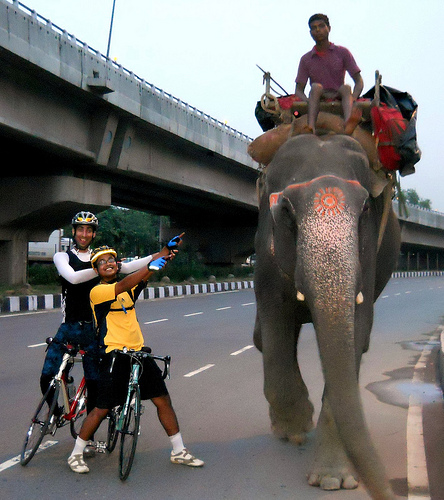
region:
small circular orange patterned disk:
[313, 183, 352, 227]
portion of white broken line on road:
[150, 303, 238, 327]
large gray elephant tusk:
[286, 173, 418, 499]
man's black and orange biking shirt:
[82, 278, 159, 361]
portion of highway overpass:
[193, 98, 243, 214]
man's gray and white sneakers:
[169, 449, 207, 473]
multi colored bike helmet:
[68, 205, 113, 232]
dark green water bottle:
[110, 405, 131, 439]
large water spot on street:
[366, 363, 443, 423]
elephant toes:
[298, 462, 374, 498]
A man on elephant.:
[240, 11, 403, 494]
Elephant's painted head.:
[268, 133, 392, 498]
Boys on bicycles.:
[16, 211, 208, 495]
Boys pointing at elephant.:
[49, 208, 201, 309]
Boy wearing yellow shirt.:
[85, 281, 167, 355]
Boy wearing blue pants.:
[37, 318, 99, 383]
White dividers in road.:
[145, 295, 249, 328]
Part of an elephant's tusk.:
[292, 282, 307, 308]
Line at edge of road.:
[399, 322, 440, 498]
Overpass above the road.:
[8, 9, 242, 213]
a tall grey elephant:
[234, 142, 416, 492]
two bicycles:
[14, 326, 159, 497]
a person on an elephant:
[295, 7, 386, 142]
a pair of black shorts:
[91, 347, 169, 402]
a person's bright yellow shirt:
[82, 281, 163, 345]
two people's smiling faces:
[47, 208, 131, 284]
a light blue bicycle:
[96, 340, 176, 484]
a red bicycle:
[19, 329, 98, 466]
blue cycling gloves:
[147, 237, 189, 282]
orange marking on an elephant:
[305, 182, 356, 224]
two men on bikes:
[18, 209, 206, 486]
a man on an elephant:
[245, 11, 423, 497]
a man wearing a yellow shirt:
[63, 241, 208, 473]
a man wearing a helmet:
[60, 241, 210, 475]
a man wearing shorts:
[64, 242, 209, 476]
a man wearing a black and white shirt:
[36, 206, 188, 460]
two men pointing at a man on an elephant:
[18, 12, 425, 498]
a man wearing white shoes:
[65, 245, 208, 478]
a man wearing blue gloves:
[62, 242, 207, 482]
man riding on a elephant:
[226, 10, 406, 446]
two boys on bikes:
[18, 195, 189, 475]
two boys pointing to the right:
[24, 182, 198, 484]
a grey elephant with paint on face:
[224, 130, 390, 496]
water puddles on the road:
[370, 316, 441, 449]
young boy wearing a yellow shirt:
[89, 242, 150, 358]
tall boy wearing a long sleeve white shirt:
[49, 210, 183, 278]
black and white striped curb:
[6, 277, 242, 308]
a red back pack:
[365, 78, 419, 172]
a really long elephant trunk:
[291, 220, 408, 498]